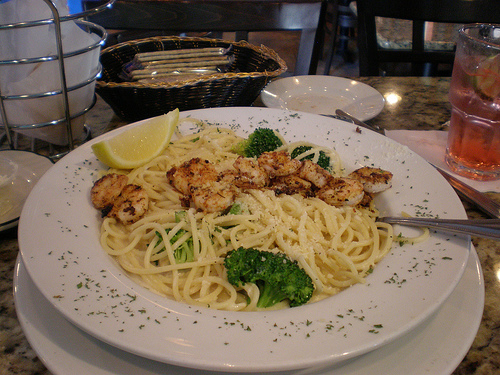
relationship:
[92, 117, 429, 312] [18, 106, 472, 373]
pasta in bowl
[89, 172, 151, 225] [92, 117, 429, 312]
chicken on pasta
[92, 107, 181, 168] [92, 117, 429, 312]
lemon on pasta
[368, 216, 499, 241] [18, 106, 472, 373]
utensil in bowl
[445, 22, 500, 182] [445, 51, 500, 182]
glass filled with liquid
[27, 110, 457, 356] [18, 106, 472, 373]
green spices on bowl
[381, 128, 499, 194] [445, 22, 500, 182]
napkin under glass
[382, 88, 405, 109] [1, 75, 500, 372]
glare on table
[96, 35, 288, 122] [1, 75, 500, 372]
basket on table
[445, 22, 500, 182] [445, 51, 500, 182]
glass has liquid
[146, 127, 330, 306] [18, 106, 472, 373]
broccoli in bowl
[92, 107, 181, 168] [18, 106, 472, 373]
lemon in bowl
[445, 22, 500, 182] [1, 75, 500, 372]
glass on table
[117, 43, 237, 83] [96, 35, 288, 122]
crackers in basket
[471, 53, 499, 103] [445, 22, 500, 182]
lime in glass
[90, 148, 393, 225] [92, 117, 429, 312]
shrimp on pasta